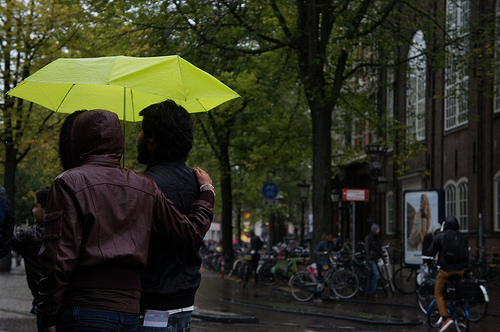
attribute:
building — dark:
[310, 0, 499, 274]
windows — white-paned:
[442, 176, 471, 232]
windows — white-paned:
[444, 0, 470, 133]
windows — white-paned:
[404, 29, 428, 145]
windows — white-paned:
[322, 3, 394, 165]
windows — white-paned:
[383, 187, 395, 237]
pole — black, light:
[296, 176, 311, 248]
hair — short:
[158, 125, 192, 154]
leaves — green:
[250, 65, 301, 170]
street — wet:
[216, 271, 311, 323]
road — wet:
[206, 281, 298, 325]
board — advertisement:
[401, 187, 441, 265]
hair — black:
[139, 98, 194, 164]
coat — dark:
[359, 230, 382, 260]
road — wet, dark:
[197, 273, 479, 330]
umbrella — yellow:
[4, 49, 241, 124]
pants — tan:
[431, 267, 464, 319]